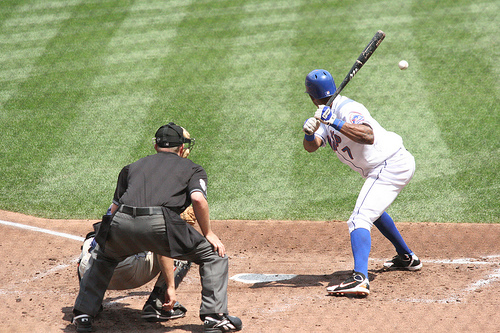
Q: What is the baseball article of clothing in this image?
A: The clothing item is a uniform.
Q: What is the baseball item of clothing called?
A: The clothing item is a uniform.